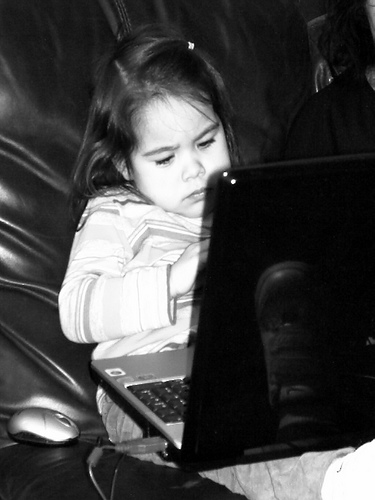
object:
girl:
[57, 31, 372, 500]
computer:
[84, 159, 372, 474]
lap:
[143, 380, 204, 472]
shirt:
[58, 189, 200, 361]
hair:
[67, 27, 243, 207]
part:
[108, 52, 135, 99]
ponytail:
[150, 39, 244, 122]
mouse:
[8, 409, 82, 444]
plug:
[92, 435, 168, 463]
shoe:
[327, 441, 375, 499]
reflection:
[259, 256, 332, 438]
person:
[290, 7, 374, 154]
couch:
[3, 4, 357, 329]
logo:
[106, 368, 126, 376]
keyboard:
[127, 374, 191, 425]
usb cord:
[84, 446, 108, 499]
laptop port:
[129, 437, 169, 452]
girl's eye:
[155, 153, 176, 166]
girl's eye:
[198, 139, 216, 147]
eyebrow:
[141, 144, 180, 158]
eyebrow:
[192, 123, 220, 142]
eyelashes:
[156, 157, 172, 164]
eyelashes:
[199, 139, 216, 147]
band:
[188, 42, 195, 51]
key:
[136, 388, 152, 396]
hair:
[319, 17, 374, 70]